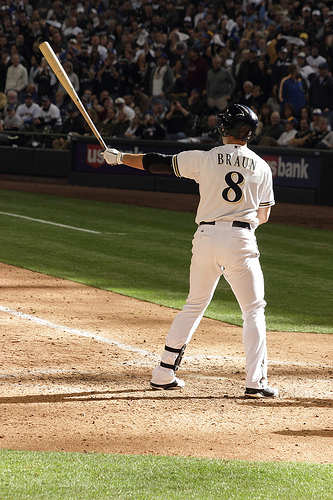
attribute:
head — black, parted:
[214, 97, 269, 142]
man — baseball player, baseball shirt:
[169, 102, 282, 404]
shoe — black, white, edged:
[230, 377, 292, 398]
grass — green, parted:
[287, 256, 309, 292]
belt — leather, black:
[204, 215, 259, 230]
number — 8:
[219, 166, 254, 206]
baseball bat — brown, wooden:
[28, 36, 107, 152]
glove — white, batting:
[100, 142, 127, 165]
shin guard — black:
[154, 332, 203, 372]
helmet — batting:
[221, 112, 258, 141]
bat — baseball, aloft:
[34, 25, 104, 82]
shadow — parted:
[19, 376, 186, 423]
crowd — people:
[122, 16, 274, 109]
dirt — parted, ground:
[59, 286, 110, 327]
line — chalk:
[58, 321, 83, 350]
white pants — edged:
[200, 229, 261, 358]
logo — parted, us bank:
[268, 153, 324, 194]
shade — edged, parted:
[184, 8, 230, 44]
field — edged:
[313, 318, 324, 327]